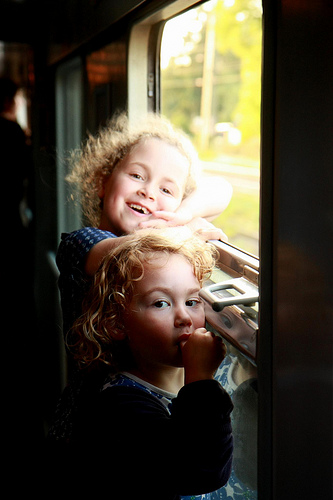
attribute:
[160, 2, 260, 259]
glass — transparent